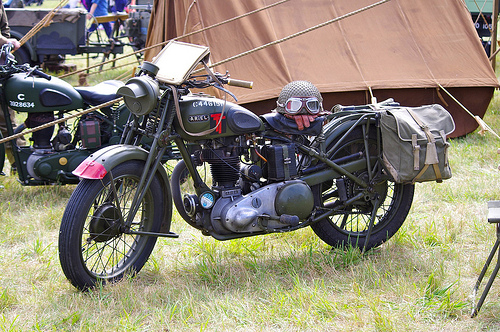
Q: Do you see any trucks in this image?
A: Yes, there is a truck.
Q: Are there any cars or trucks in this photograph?
A: Yes, there is a truck.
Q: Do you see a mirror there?
A: No, there are no mirrors.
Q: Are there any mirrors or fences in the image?
A: No, there are no mirrors or fences.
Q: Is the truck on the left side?
A: Yes, the truck is on the left of the image.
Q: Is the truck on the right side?
A: No, the truck is on the left of the image.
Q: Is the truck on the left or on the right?
A: The truck is on the left of the image.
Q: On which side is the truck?
A: The truck is on the left of the image.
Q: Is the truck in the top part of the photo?
A: Yes, the truck is in the top of the image.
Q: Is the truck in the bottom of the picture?
A: No, the truck is in the top of the image.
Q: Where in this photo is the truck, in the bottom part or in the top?
A: The truck is in the top of the image.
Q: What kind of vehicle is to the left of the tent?
A: The vehicle is a truck.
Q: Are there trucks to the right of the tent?
A: No, the truck is to the left of the tent.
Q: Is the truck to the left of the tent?
A: Yes, the truck is to the left of the tent.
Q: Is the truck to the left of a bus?
A: No, the truck is to the left of the tent.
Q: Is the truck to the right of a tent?
A: No, the truck is to the left of a tent.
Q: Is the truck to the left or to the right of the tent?
A: The truck is to the left of the tent.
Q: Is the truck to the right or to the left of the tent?
A: The truck is to the left of the tent.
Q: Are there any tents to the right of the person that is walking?
A: Yes, there is a tent to the right of the person.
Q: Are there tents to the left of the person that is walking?
A: No, the tent is to the right of the person.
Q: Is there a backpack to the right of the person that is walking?
A: No, there is a tent to the right of the person.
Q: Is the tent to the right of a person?
A: Yes, the tent is to the right of a person.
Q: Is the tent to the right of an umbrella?
A: No, the tent is to the right of a person.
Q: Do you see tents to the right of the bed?
A: Yes, there is a tent to the right of the bed.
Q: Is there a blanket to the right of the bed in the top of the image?
A: No, there is a tent to the right of the bed.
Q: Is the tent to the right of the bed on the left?
A: Yes, the tent is to the right of the bed.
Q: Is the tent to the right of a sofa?
A: No, the tent is to the right of the bed.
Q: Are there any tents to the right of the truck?
A: Yes, there is a tent to the right of the truck.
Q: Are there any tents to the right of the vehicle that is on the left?
A: Yes, there is a tent to the right of the truck.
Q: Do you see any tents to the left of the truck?
A: No, the tent is to the right of the truck.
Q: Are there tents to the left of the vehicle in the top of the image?
A: No, the tent is to the right of the truck.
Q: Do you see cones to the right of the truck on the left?
A: No, there is a tent to the right of the truck.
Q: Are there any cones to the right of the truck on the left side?
A: No, there is a tent to the right of the truck.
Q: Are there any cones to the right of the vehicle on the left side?
A: No, there is a tent to the right of the truck.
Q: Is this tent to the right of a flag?
A: No, the tent is to the right of a truck.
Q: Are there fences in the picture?
A: No, there are no fences.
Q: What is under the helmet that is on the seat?
A: The glove is under the helmet.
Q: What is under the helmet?
A: The glove is under the helmet.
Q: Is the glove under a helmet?
A: Yes, the glove is under a helmet.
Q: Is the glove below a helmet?
A: Yes, the glove is below a helmet.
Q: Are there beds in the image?
A: Yes, there is a bed.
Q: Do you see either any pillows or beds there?
A: Yes, there is a bed.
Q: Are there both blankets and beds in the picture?
A: No, there is a bed but no blankets.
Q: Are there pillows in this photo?
A: No, there are no pillows.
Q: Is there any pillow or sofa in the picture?
A: No, there are no pillows or sofas.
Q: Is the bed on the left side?
A: Yes, the bed is on the left of the image.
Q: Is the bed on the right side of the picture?
A: No, the bed is on the left of the image.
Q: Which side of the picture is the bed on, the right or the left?
A: The bed is on the left of the image.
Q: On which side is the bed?
A: The bed is on the left of the image.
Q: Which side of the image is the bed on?
A: The bed is on the left of the image.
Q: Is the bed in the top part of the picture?
A: Yes, the bed is in the top of the image.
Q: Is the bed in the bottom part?
A: No, the bed is in the top of the image.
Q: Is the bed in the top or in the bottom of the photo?
A: The bed is in the top of the image.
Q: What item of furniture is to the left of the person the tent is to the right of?
A: The piece of furniture is a bed.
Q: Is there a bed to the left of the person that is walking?
A: Yes, there is a bed to the left of the person.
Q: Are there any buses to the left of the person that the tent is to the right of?
A: No, there is a bed to the left of the person.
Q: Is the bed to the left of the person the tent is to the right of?
A: Yes, the bed is to the left of the person.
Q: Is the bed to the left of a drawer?
A: No, the bed is to the left of the person.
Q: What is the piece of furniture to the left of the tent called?
A: The piece of furniture is a bed.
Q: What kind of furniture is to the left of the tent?
A: The piece of furniture is a bed.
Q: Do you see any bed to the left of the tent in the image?
A: Yes, there is a bed to the left of the tent.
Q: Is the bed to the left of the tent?
A: Yes, the bed is to the left of the tent.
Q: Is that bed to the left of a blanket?
A: No, the bed is to the left of the tent.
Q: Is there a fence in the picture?
A: No, there are no fences.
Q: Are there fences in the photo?
A: No, there are no fences.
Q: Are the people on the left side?
A: Yes, the people are on the left of the image.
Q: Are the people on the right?
A: No, the people are on the left of the image.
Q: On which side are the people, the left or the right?
A: The people are on the left of the image.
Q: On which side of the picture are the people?
A: The people are on the left of the image.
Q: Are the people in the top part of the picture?
A: Yes, the people are in the top of the image.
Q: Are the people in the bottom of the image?
A: No, the people are in the top of the image.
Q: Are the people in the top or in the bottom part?
A: The people are in the top of the image.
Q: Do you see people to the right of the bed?
A: Yes, there are people to the right of the bed.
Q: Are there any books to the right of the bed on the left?
A: No, there are people to the right of the bed.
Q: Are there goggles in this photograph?
A: Yes, there are goggles.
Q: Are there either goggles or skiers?
A: Yes, there are goggles.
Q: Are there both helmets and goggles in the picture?
A: Yes, there are both goggles and a helmet.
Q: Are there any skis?
A: No, there are no skis.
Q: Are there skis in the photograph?
A: No, there are no skis.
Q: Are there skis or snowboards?
A: No, there are no skis or snowboards.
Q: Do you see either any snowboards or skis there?
A: No, there are no skis or snowboards.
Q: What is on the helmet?
A: The goggles are on the helmet.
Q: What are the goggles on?
A: The goggles are on the helmet.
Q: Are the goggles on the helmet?
A: Yes, the goggles are on the helmet.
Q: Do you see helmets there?
A: Yes, there is a helmet.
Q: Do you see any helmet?
A: Yes, there is a helmet.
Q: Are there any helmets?
A: Yes, there is a helmet.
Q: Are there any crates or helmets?
A: Yes, there is a helmet.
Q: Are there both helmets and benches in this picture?
A: No, there is a helmet but no benches.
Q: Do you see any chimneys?
A: No, there are no chimneys.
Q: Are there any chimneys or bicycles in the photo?
A: No, there are no chimneys or bicycles.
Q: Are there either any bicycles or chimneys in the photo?
A: No, there are no chimneys or bicycles.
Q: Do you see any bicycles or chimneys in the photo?
A: No, there are no chimneys or bicycles.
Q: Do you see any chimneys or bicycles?
A: No, there are no chimneys or bicycles.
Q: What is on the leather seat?
A: The helmet is on the seat.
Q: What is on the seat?
A: The helmet is on the seat.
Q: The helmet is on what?
A: The helmet is on the seat.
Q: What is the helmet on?
A: The helmet is on the seat.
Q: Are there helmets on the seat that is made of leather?
A: Yes, there is a helmet on the seat.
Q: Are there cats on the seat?
A: No, there is a helmet on the seat.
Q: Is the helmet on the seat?
A: Yes, the helmet is on the seat.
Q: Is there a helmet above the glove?
A: Yes, there is a helmet above the glove.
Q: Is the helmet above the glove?
A: Yes, the helmet is above the glove.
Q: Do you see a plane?
A: No, there are no airplanes.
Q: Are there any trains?
A: No, there are no trains.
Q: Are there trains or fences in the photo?
A: No, there are no trains or fences.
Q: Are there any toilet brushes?
A: No, there are no toilet brushes.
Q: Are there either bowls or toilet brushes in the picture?
A: No, there are no toilet brushes or bowls.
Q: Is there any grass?
A: Yes, there is grass.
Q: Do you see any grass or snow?
A: Yes, there is grass.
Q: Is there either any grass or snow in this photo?
A: Yes, there is grass.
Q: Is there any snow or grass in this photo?
A: Yes, there is grass.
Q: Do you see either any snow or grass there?
A: Yes, there is grass.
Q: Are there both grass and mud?
A: No, there is grass but no mud.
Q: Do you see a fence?
A: No, there are no fences.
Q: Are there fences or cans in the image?
A: No, there are no fences or cans.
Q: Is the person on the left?
A: Yes, the person is on the left of the image.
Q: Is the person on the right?
A: No, the person is on the left of the image.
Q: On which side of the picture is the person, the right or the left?
A: The person is on the left of the image.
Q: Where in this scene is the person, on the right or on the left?
A: The person is on the left of the image.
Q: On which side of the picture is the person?
A: The person is on the left of the image.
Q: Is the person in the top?
A: Yes, the person is in the top of the image.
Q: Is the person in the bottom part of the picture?
A: No, the person is in the top of the image.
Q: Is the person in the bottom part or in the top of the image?
A: The person is in the top of the image.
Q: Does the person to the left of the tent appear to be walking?
A: Yes, the person is walking.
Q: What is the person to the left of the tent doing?
A: The person is walking.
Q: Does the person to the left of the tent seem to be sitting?
A: No, the person is walking.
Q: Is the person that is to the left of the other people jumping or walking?
A: The person is walking.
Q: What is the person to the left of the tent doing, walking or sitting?
A: The person is walking.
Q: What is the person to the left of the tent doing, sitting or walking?
A: The person is walking.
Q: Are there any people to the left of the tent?
A: Yes, there is a person to the left of the tent.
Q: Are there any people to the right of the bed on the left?
A: Yes, there is a person to the right of the bed.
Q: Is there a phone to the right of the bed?
A: No, there is a person to the right of the bed.